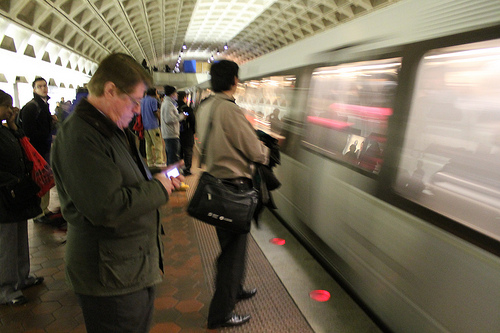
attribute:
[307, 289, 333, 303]
light — red, circle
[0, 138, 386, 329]
ground — red, brown tile, tile, brown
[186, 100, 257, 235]
shoulder bag — black leather, black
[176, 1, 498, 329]
train — moving, in motion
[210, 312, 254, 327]
shoe — black, shiny, shiny black, leather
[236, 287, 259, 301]
shoe — black, shiny, shiny black, leather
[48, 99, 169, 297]
jacket — dark green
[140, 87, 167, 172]
man — standing, waiting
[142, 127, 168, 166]
pants — khaki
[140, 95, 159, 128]
shirt — blue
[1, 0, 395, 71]
ceiling — geometric shaped, coffered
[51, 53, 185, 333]
man — older, standing, blonde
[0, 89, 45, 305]
woman — standing, waiting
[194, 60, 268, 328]
man — standing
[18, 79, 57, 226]
person — standing, waiting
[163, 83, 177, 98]
hat — black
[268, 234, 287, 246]
light — red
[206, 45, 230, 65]
lights — white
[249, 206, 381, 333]
stripe — gray